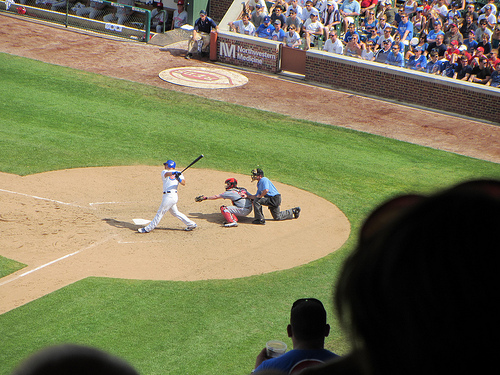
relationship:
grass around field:
[44, 100, 82, 141] [66, 43, 98, 63]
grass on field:
[44, 100, 82, 141] [66, 43, 98, 63]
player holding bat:
[145, 155, 193, 239] [177, 142, 206, 170]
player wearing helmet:
[145, 155, 193, 239] [162, 160, 174, 170]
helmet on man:
[162, 160, 174, 170] [239, 152, 297, 237]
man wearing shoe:
[239, 152, 297, 237] [181, 48, 199, 60]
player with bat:
[145, 155, 193, 239] [177, 142, 206, 170]